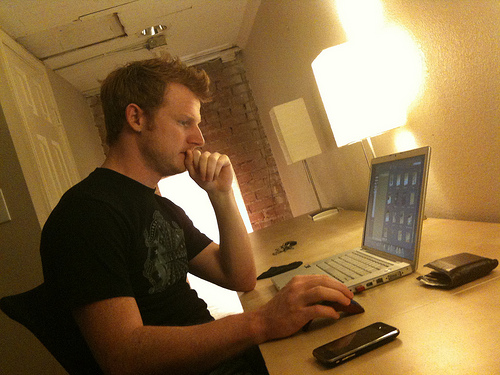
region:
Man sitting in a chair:
[39, 56, 357, 374]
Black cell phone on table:
[312, 321, 400, 368]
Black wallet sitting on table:
[416, 249, 497, 297]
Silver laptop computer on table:
[269, 145, 434, 300]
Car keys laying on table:
[269, 238, 297, 258]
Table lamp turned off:
[267, 96, 342, 225]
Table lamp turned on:
[309, 35, 408, 165]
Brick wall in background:
[182, 51, 301, 226]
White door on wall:
[1, 31, 83, 228]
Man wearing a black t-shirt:
[38, 49, 356, 374]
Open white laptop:
[269, 143, 429, 301]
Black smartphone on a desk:
[312, 319, 399, 369]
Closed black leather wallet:
[414, 251, 498, 293]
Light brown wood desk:
[220, 206, 495, 372]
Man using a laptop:
[36, 50, 352, 372]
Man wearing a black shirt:
[38, 50, 354, 374]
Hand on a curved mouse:
[256, 272, 365, 337]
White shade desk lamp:
[268, 100, 338, 226]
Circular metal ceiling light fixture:
[135, 20, 166, 38]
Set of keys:
[269, 238, 298, 255]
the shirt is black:
[81, 220, 100, 245]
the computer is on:
[389, 190, 408, 215]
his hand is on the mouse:
[333, 288, 366, 313]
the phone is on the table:
[355, 338, 388, 355]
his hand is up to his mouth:
[176, 143, 201, 165]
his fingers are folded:
[197, 163, 224, 183]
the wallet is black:
[444, 256, 472, 267]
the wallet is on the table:
[432, 263, 462, 295]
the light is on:
[336, 62, 375, 101]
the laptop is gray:
[326, 258, 348, 277]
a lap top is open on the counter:
[268, 143, 435, 315]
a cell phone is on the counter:
[308, 315, 403, 370]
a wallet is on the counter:
[413, 234, 498, 295]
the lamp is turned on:
[301, 28, 413, 150]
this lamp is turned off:
[250, 87, 335, 224]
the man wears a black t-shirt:
[25, 163, 220, 372]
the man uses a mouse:
[271, 280, 351, 334]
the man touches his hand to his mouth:
[161, 135, 234, 192]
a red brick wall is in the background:
[184, 63, 282, 224]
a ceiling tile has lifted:
[20, 4, 130, 65]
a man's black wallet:
[418, 248, 498, 287]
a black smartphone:
[309, 320, 400, 366]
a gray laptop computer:
[266, 140, 437, 310]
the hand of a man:
[177, 148, 235, 195]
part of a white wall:
[428, 46, 498, 153]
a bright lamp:
[304, 40, 419, 145]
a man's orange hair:
[91, 52, 215, 153]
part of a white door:
[5, 43, 82, 209]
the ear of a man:
[124, 100, 150, 135]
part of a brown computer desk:
[419, 214, 497, 255]